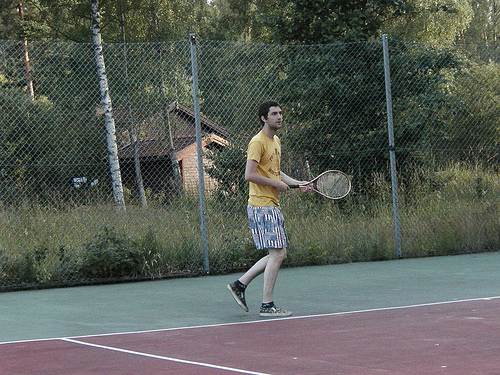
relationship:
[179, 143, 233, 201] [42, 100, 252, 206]
wall near building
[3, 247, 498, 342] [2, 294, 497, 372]
pavement of tennis court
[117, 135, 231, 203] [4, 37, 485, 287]
building behind fence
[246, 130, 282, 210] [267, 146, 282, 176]
t-shirt with letters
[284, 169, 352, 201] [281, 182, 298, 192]
tennis racquet with black grip